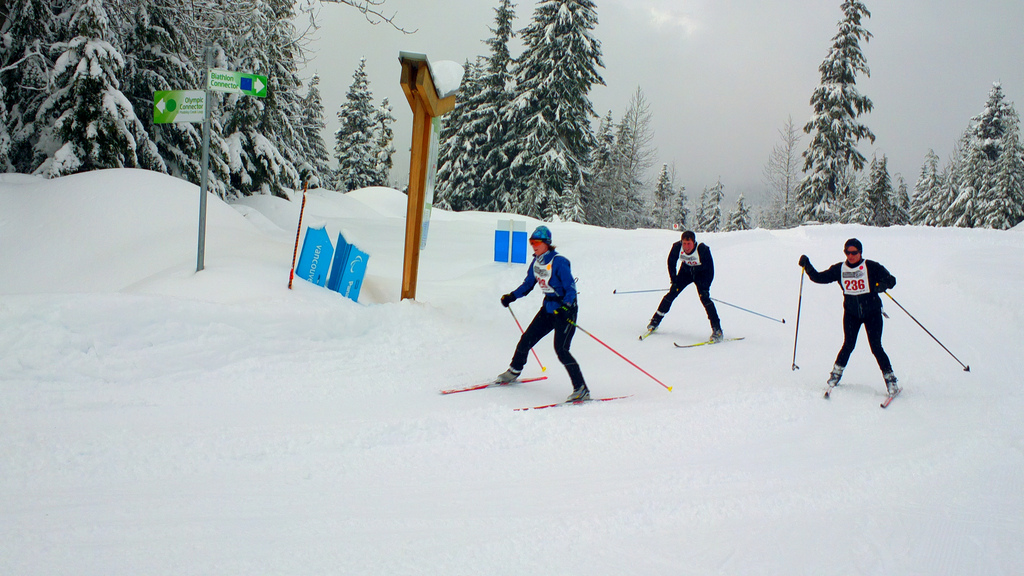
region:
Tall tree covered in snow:
[330, 53, 379, 193]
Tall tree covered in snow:
[291, 73, 329, 187]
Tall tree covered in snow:
[438, 0, 522, 210]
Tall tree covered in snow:
[580, 88, 648, 224]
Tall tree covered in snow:
[643, 162, 678, 232]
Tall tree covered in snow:
[668, 173, 698, 235]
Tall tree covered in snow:
[788, 2, 875, 228]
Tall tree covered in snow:
[958, 81, 1022, 227]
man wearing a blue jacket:
[525, 249, 579, 313]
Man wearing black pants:
[505, 303, 586, 380]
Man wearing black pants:
[647, 271, 736, 325]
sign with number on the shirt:
[827, 256, 873, 302]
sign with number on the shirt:
[525, 260, 567, 296]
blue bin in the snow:
[296, 215, 345, 288]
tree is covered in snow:
[497, 1, 608, 223]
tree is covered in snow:
[598, 86, 653, 230]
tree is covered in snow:
[801, 3, 878, 220]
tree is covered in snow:
[861, 156, 907, 220]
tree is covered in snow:
[336, 60, 381, 187]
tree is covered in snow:
[370, 98, 396, 181]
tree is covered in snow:
[298, 71, 336, 180]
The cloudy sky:
[278, 4, 1019, 197]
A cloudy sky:
[299, 3, 1015, 203]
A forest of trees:
[13, 4, 1022, 277]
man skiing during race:
[479, 209, 584, 419]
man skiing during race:
[617, 218, 731, 349]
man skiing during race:
[775, 236, 930, 396]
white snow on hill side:
[29, 399, 93, 454]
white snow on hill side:
[506, 493, 599, 563]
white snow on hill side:
[661, 496, 734, 569]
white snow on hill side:
[760, 490, 862, 566]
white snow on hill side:
[260, 341, 365, 440]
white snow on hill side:
[172, 437, 250, 492]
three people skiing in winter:
[436, 221, 983, 428]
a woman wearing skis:
[786, 237, 983, 419]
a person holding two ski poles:
[609, 224, 790, 361]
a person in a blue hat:
[439, 219, 678, 416]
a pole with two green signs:
[149, 45, 266, 279]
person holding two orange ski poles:
[433, 221, 675, 418]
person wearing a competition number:
[789, 231, 977, 408]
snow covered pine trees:
[781, 0, 1020, 226]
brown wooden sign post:
[392, 45, 460, 301]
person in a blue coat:
[505, 222, 592, 403]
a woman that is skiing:
[438, 223, 679, 416]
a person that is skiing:
[791, 238, 975, 413]